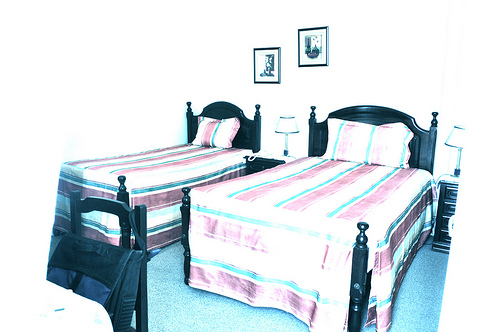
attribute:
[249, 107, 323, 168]
lamp — small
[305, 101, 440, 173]
head board — black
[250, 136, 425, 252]
bedpsread — striped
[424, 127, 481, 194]
lamp — small, white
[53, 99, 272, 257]
twinbed — black, framed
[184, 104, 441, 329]
twinbed — black, framed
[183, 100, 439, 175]
headboards — black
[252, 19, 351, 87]
picture — framed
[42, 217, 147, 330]
bag — black, blue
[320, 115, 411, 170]
pillow cover — striped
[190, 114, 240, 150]
pillow cover — striped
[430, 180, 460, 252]
black nightstand — small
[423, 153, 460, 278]
stand — wooden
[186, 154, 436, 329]
bedspread — striped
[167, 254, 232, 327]
carpet — blue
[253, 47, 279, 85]
picture — above